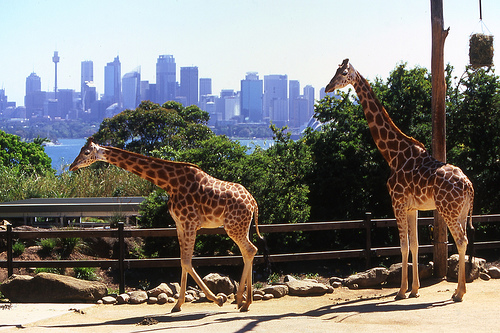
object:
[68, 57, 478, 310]
giraffes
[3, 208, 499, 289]
fence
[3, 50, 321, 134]
buildings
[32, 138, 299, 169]
water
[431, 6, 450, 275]
pole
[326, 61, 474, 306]
giraffe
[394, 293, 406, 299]
feet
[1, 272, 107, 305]
rocks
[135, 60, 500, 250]
bushes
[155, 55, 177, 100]
building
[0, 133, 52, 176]
trees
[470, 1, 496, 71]
feeder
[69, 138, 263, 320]
giraffe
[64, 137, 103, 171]
head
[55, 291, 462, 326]
shadows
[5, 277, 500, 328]
ground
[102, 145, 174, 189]
neck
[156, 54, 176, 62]
roof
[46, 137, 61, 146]
boat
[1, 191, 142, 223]
tracks